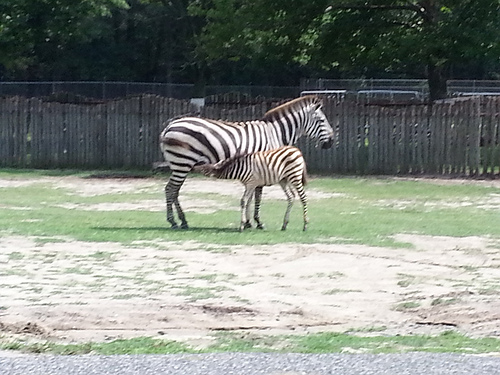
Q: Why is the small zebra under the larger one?
A: It is nursing.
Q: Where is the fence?
A: Behind the zebras.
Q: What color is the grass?
A: Green.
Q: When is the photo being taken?
A: Day time.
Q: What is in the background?
A: Trees.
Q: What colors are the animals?
A: Black and white.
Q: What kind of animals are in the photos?
A: Zebras.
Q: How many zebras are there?
A: Two.